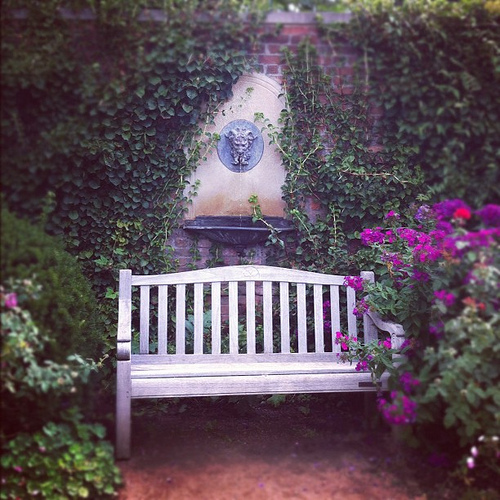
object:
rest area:
[113, 257, 403, 460]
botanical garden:
[0, 0, 500, 498]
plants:
[0, 0, 270, 306]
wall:
[2, 14, 500, 320]